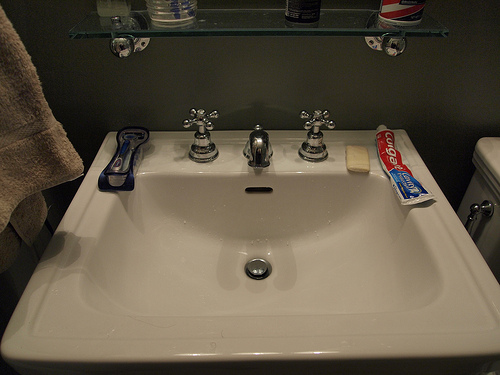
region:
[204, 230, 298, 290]
drain in the sink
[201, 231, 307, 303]
shadows in the sink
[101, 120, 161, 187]
razor on the sink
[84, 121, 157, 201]
razor holder on the sink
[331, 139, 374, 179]
soap on the sink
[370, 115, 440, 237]
toothpaste on the sink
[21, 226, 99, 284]
shadow of the towel on the sink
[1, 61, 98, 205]
corner of the towel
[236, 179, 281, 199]
overflow drain in the sink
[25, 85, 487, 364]
sink against the wall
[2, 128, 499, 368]
A white bathroom sink.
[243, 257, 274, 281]
The drain of a sink.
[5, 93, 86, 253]
Towel hanging on the bathroom wall.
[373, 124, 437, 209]
A tube of toothpaste.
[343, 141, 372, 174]
A bar of soap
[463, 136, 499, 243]
The side of a toilet.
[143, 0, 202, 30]
The bottom of a glass on a shelf.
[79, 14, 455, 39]
A shelf above the sink.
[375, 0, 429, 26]
The bottom of a can of shaving cream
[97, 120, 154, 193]
A razor.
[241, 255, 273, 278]
A silver sink drain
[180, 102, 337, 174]
Sink furnishing stainless steele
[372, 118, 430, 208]
Red and blue toothepaste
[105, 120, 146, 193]
A mens shaving razor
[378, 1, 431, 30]
Bottom of shaving foam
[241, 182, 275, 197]
Sink overflow drain hole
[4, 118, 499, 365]
A sink with toiletries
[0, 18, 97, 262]
A brown wash towel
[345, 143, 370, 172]
Yellow body soap for washing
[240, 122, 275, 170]
Sink faucet drain fixture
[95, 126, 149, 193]
Blue razor in a container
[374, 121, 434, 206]
Large tube of Colgate toothpaste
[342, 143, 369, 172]
Used cream color bar of soap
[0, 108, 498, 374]
White square shaped sink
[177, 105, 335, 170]
Two silver sink knobs with silver faucet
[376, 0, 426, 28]
Red and white striped shaving cream can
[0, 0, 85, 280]
Tan colored bathroom towel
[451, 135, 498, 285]
White toilet with silver handle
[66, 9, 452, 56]
Glass shelf above the sink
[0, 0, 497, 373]
Bathroom with hygiene items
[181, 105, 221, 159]
knob on the sink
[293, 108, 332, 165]
knob on the sink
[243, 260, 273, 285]
drain on the sink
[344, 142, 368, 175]
bar of soap on sink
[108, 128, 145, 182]
razer on the sink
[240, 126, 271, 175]
faucet on the sink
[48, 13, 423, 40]
shelf above the sink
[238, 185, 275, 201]
opening in the sink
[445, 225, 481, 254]
ledge of the sink